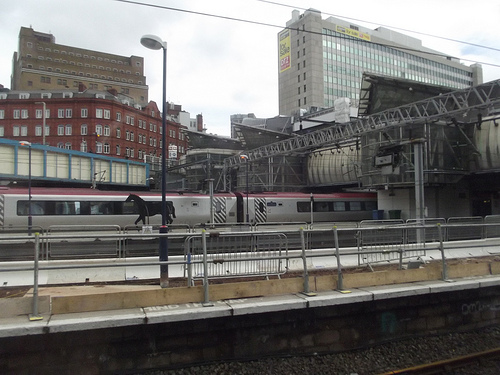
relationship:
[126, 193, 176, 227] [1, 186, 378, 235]
horse in front of train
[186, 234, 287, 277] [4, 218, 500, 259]
gate near tracks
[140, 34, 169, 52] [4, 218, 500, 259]
light near tracks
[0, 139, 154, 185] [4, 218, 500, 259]
building near tracks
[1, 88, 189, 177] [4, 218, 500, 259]
building near tracks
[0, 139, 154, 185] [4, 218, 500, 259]
building behind tracks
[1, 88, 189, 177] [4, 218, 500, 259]
building behind tracks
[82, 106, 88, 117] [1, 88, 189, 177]
window on building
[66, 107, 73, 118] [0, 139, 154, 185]
window on building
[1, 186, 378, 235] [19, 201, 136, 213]
train has window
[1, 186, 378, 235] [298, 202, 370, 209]
train has window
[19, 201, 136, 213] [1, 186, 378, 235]
window on train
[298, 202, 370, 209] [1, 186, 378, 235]
window on train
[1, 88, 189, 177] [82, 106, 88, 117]
building has window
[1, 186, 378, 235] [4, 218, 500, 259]
train near tracks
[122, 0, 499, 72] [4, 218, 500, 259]
wire over tracks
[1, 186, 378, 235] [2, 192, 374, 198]
train has top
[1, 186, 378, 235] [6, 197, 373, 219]
train has side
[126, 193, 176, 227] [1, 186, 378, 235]
horse near train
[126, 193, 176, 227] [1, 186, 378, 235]
horse on side of train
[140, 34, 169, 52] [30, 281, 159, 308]
light above platform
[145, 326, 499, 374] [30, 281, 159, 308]
gravel beneath platform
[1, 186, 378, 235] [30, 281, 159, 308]
train across from platform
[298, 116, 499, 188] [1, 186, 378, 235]
walkway above train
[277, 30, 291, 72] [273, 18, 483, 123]
advertisement on building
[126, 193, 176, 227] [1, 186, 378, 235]
horse beside train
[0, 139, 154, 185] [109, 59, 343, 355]
building in city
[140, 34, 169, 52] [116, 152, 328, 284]
light of street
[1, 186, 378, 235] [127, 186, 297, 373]
train near road